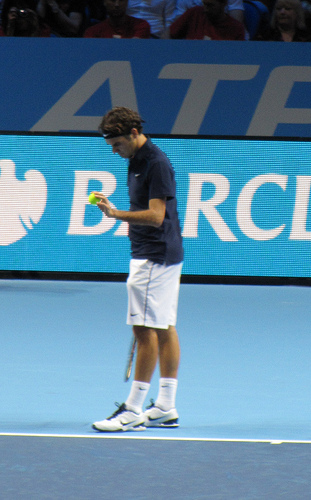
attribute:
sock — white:
[154, 377, 177, 410]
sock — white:
[124, 379, 150, 411]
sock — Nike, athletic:
[122, 382, 150, 416]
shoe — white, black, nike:
[91, 400, 145, 431]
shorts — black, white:
[103, 261, 191, 324]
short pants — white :
[122, 252, 181, 329]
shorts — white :
[120, 253, 180, 328]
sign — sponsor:
[51, 130, 276, 278]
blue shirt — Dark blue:
[126, 151, 182, 260]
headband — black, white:
[94, 122, 146, 137]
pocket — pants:
[138, 254, 167, 272]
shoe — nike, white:
[144, 397, 179, 427]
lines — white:
[66, 420, 308, 459]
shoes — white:
[86, 403, 186, 430]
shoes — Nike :
[92, 400, 183, 434]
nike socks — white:
[124, 372, 177, 411]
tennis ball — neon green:
[87, 192, 100, 204]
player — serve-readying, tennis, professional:
[88, 108, 181, 435]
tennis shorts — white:
[124, 253, 183, 327]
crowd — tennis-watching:
[1, 2, 310, 41]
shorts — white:
[124, 252, 185, 330]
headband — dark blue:
[102, 127, 140, 136]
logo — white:
[0, 156, 310, 251]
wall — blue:
[0, 133, 310, 280]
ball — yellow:
[59, 167, 122, 236]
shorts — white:
[107, 247, 232, 353]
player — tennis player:
[92, 103, 183, 298]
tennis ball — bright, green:
[88, 193, 99, 204]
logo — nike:
[136, 382, 148, 392]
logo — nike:
[158, 382, 168, 389]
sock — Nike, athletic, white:
[151, 376, 177, 411]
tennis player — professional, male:
[90, 104, 186, 431]